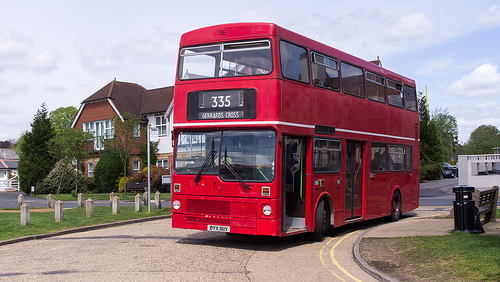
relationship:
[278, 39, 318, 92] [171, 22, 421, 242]
window on bus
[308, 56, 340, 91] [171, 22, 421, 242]
window on bus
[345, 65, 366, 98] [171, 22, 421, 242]
window on bus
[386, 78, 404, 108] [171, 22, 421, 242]
window on bus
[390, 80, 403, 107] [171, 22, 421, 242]
window on bus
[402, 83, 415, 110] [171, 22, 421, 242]
window on bus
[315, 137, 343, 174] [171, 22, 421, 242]
window on bus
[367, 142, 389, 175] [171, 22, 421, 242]
window on bus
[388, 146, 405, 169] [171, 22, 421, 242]
window on bus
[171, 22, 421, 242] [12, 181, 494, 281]
bus on road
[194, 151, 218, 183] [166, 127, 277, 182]
windhsield wiper over windshield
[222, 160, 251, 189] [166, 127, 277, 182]
windshield wiper over windshield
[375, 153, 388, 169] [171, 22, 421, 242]
person inside bus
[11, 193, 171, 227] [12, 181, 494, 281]
fence on road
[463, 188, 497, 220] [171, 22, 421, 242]
bench next to bus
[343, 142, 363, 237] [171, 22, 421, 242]
double door on a bus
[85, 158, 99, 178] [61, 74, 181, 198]
window in a building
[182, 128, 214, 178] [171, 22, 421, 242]
windshield wiper on a bus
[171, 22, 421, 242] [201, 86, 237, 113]
bus has a number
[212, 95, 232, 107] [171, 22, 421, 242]
335 printed on a bus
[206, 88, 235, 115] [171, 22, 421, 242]
335 printed on a bus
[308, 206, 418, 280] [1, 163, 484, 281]
line on road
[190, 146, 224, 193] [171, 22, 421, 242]
windhsield wiper on bus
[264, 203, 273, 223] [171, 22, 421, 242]
light on bus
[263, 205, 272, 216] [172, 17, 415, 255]
light on bus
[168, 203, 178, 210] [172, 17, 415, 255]
light on bus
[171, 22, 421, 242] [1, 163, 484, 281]
bus on road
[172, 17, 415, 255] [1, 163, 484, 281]
bus on road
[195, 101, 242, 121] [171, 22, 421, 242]
text printed on a bus